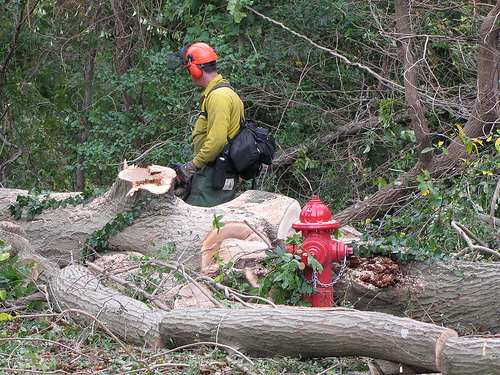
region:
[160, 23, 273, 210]
Man cuttind down trees in woods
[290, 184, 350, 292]
red fire hydrant in woods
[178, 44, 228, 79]
Orange safety helmet on worker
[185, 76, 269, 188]
Yellow long sleeved jacket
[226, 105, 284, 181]
Black backpack on worker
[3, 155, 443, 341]
Fallen chopped trees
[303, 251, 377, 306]
Metal chain on hydrant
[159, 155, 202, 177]
Gray work gloves on man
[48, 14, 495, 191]
Thick brush in background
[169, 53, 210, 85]
Orange ear muffs on worker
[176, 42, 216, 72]
A red helmet in the photo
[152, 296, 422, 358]
A log in the photo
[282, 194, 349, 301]
A fire hydrant in the photo.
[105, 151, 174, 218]
A tree stump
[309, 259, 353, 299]
A chain on the hydrant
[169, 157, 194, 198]
A power saw in the photo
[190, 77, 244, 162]
A yellow sweater in the photo.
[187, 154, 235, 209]
A black pant in the photo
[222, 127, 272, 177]
A backpack in the photo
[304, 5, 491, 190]
Trees in the forest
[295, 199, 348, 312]
red fire hydrant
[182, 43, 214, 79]
orange hat on man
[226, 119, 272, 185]
black backpack on man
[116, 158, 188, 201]
cut tree branch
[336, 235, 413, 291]
knot of cut down tree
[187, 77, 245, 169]
yellow shirt on man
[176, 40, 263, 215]
man in yellow shirt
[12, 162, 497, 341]
cut down tree trunk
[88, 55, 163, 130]
leaves in the background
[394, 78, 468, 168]
tree branches in the background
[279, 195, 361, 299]
Fire hydrant near the tree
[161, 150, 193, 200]
A person holding the axe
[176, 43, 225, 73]
A person wearing orange color helmet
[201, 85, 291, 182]
A person with black color backpack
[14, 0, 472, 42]
Lot of trees near the person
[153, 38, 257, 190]
A person standing near the tree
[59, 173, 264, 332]
Lumbering tree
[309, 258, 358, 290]
A metal chain in the fire hydrant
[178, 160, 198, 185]
A person wearing glove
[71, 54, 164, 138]
Green leaves in the tree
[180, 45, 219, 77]
Man with orange helmet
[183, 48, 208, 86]
Man wearing ear protection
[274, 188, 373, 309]
red fire hydrant next to trees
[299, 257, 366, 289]
chain on a fire hydrant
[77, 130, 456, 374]
Wood tree trunk in field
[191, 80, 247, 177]
Man wearing yellow shirt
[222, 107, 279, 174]
Man with a backpack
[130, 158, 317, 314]
chopped up trees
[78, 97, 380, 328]
Wood and trees in the field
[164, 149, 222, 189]
Man wearing gloves